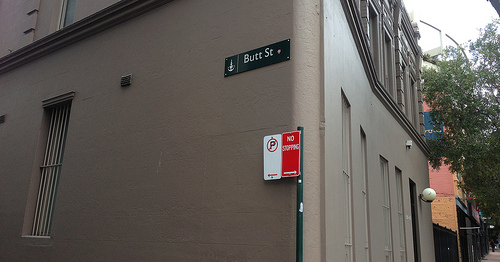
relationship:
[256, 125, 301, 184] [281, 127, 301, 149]
sign says no parking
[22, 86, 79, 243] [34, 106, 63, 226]
window has bars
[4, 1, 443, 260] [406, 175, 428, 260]
building has door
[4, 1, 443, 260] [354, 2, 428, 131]
building has windows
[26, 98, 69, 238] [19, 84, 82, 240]
bars on window